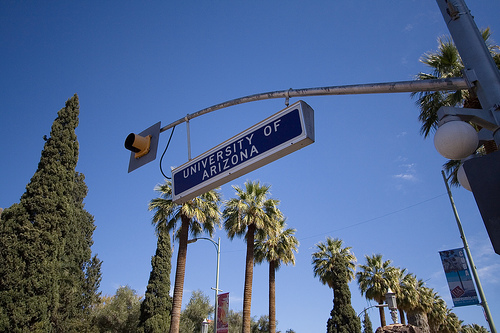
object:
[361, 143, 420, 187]
cloud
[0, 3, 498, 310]
sky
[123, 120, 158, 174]
light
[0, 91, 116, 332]
trees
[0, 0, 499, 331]
photo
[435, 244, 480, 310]
banner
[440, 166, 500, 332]
pole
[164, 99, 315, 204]
sign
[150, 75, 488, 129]
pole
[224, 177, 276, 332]
tree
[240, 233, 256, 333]
trunk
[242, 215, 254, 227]
leaves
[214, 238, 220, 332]
pole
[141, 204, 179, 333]
pine tree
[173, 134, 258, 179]
university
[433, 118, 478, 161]
lamp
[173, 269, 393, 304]
row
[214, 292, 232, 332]
banner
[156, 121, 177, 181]
wire